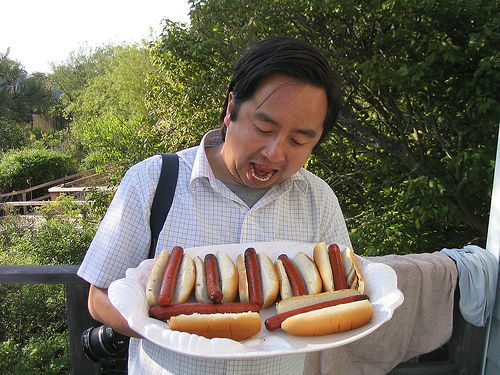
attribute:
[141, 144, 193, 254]
shoulder — man's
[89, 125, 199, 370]
camera — black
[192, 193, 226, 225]
shirt — checkered, white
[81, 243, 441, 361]
tray — white, large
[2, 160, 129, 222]
boardwalk — wood, light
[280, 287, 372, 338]
bun — white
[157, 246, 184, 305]
hot dog — grilled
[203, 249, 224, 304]
hot dog — grilled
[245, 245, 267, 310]
hot dog — grilled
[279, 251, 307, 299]
hot dog — grilled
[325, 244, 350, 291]
hot dog — grilled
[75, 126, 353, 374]
shirt — plaid, white